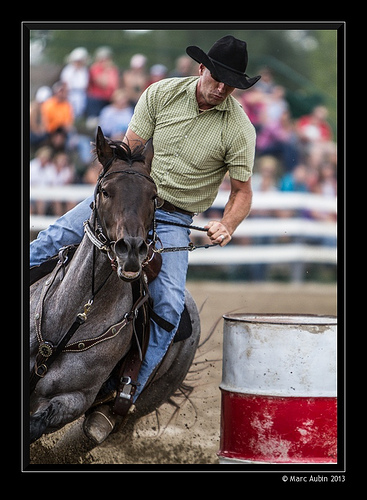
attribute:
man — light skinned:
[30, 34, 262, 444]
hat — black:
[183, 32, 262, 92]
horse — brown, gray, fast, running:
[29, 125, 201, 449]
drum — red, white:
[220, 308, 337, 463]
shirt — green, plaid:
[128, 75, 258, 214]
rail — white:
[28, 179, 338, 213]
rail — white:
[28, 213, 336, 240]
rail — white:
[185, 243, 335, 267]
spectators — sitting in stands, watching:
[29, 41, 336, 280]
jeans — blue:
[29, 190, 194, 406]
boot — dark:
[80, 393, 120, 444]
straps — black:
[83, 169, 165, 281]